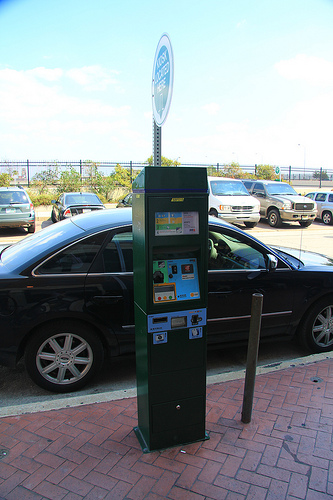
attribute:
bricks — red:
[237, 450, 261, 471]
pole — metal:
[240, 293, 264, 423]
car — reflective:
[1, 207, 332, 396]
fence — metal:
[28, 162, 135, 181]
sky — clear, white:
[190, 15, 306, 88]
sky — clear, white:
[61, 6, 126, 59]